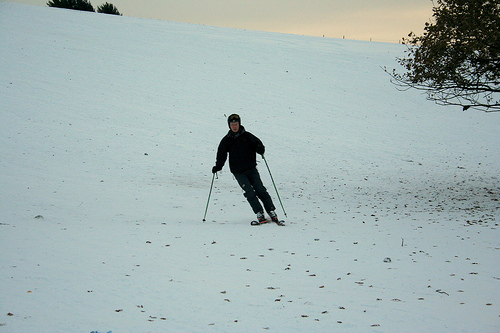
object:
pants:
[230, 163, 277, 214]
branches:
[425, 95, 499, 110]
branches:
[460, 52, 499, 72]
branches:
[381, 66, 499, 95]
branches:
[447, 3, 499, 47]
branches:
[407, 32, 478, 40]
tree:
[383, 2, 499, 117]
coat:
[215, 125, 266, 174]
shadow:
[366, 147, 497, 235]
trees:
[95, 0, 122, 15]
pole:
[201, 172, 217, 222]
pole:
[259, 151, 287, 216]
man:
[212, 114, 277, 224]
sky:
[25, 0, 446, 43]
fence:
[322, 34, 403, 44]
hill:
[0, 1, 499, 331]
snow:
[4, 2, 495, 332]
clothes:
[211, 125, 276, 214]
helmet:
[227, 113, 241, 127]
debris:
[411, 251, 418, 255]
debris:
[476, 218, 485, 223]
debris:
[483, 187, 490, 192]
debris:
[264, 282, 280, 293]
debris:
[239, 255, 251, 261]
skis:
[271, 217, 285, 226]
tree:
[44, 0, 96, 12]